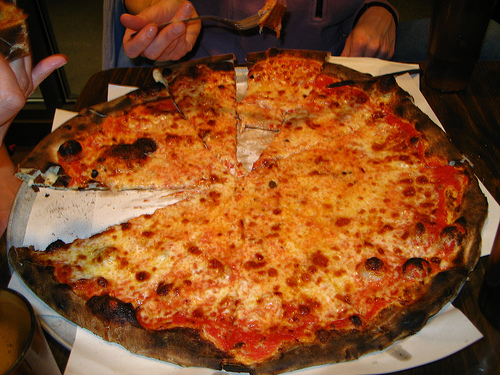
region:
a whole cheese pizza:
[51, 62, 431, 372]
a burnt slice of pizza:
[35, 91, 150, 202]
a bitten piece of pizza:
[248, 53, 313, 134]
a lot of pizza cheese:
[100, 232, 161, 286]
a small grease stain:
[45, 196, 109, 223]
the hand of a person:
[115, 8, 206, 62]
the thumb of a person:
[30, 45, 80, 92]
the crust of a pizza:
[44, 245, 89, 330]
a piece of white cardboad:
[415, 305, 490, 356]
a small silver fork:
[180, 6, 292, 33]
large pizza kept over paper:
[40, 104, 465, 313]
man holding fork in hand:
[126, 10, 274, 43]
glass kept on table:
[0, 296, 45, 372]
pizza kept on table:
[65, 75, 486, 366]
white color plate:
[17, 188, 65, 240]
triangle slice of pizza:
[208, 57, 234, 149]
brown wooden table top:
[90, 74, 148, 88]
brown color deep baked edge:
[61, 297, 139, 347]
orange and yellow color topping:
[261, 157, 369, 274]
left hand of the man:
[343, 3, 408, 58]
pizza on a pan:
[6, 50, 498, 371]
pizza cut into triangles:
[5, 45, 499, 369]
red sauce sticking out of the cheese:
[177, 307, 305, 364]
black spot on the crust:
[86, 290, 143, 323]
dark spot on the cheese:
[125, 130, 162, 157]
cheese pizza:
[2, 40, 474, 373]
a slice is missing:
[7, 165, 242, 260]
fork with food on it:
[147, 0, 290, 50]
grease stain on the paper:
[385, 343, 412, 363]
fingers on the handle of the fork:
[115, 5, 210, 62]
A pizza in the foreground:
[4, 32, 493, 374]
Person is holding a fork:
[113, 2, 292, 68]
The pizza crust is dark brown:
[6, 42, 491, 369]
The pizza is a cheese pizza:
[6, 29, 497, 374]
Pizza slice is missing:
[9, 135, 226, 277]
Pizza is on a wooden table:
[5, 47, 496, 369]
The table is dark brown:
[42, 50, 493, 370]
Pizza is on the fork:
[220, 2, 290, 52]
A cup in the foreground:
[0, 270, 75, 374]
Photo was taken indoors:
[1, 3, 497, 368]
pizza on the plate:
[137, 115, 437, 347]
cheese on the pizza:
[97, 213, 277, 320]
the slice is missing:
[21, 174, 171, 236]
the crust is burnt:
[60, 284, 224, 350]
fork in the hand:
[124, 0, 234, 67]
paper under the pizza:
[329, 293, 481, 359]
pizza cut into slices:
[97, 195, 399, 357]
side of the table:
[32, 83, 74, 130]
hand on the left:
[2, 53, 74, 112]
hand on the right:
[346, 0, 407, 62]